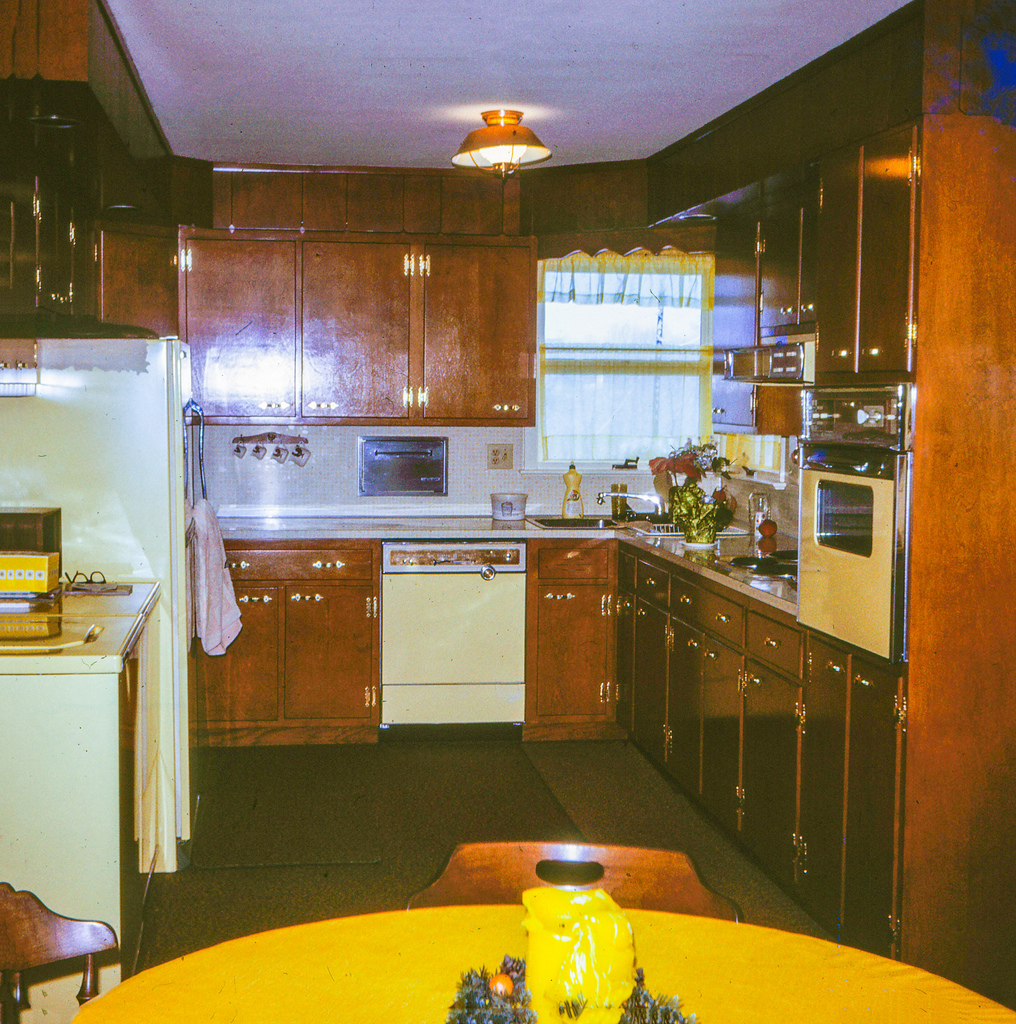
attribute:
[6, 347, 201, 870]
refrigerator — old, yellow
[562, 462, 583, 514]
bottle — yellow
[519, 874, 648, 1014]
candle — yellow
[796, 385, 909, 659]
oven — old, yellow, sliver, cream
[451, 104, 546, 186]
light — illuminated 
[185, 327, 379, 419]
light — shining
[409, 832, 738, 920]
chair — brown, wooden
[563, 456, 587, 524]
bottle — yellow, dish detergent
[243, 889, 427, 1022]
table — yellow 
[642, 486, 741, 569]
pots — gold, foil covered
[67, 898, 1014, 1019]
table — round, yellow, wooden